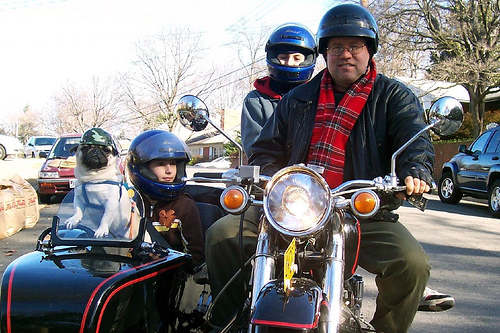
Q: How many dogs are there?
A: 1.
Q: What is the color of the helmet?
A: Black.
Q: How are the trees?
A: Without leaves.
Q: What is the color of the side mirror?
A: Silver.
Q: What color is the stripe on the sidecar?
A: Red.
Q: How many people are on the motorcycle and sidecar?
A: 3.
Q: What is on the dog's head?
A: A helmet.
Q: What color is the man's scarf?
A: Red with stripes.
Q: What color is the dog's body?
A: White.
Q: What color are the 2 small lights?
A: Orange.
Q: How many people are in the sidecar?
A: 1.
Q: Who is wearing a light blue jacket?
A: The person on the back of the motorcycle.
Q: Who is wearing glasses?
A: The man on the front of the motorcycle.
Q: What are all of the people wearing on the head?
A: Helmets.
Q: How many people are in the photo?
A: Three.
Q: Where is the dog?
A: In the motorcycle side car.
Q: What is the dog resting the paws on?
A: Steering wheel.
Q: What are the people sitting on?
A: Motorcycle with side car.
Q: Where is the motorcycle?
A: Street.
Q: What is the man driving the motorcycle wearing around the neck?
A: Scarf.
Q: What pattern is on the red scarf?
A: Plaid.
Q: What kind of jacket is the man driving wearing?
A: Leather jacket.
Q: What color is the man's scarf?
A: Red.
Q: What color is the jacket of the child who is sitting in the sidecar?
A: Brown.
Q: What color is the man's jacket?
A: Black.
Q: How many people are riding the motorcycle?
A: Three.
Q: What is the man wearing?
A: A red scarf.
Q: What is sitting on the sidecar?
A: A dog.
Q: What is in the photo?
A: Cars.